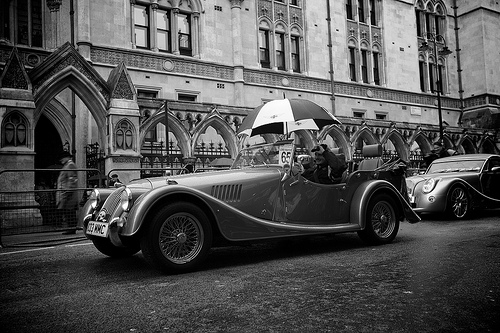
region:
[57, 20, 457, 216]
the photo is in black and white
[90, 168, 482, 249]
the car is antique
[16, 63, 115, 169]
the doorway is arched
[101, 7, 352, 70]
windows are on the building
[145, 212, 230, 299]
the wheels have chrome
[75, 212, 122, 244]
the license plate is on the front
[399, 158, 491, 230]
a car is behind the first car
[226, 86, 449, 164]
the man is holding an umbrella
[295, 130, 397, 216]
a man is saving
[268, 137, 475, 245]
the man is driving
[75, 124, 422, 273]
Man driving an old sports car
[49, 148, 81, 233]
A man is on the sidewalk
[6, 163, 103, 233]
A metal barricade on the sidewalk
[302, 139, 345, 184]
Driver waving to the crowd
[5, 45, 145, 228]
Archway on the sidewalk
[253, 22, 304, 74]
Windows on the building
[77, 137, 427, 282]
Car driving on the asphalt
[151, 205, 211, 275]
Car has metallic rims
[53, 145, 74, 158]
Man wearing a hat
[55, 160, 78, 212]
Man wearing a coat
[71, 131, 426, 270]
vintage car parked next to building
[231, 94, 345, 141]
black and white umbrella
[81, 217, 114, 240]
black and white license plate on front of car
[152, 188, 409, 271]
two wheels on side of vintage car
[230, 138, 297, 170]
windshield on vintage car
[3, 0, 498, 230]
stone building in front of sidewalk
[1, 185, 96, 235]
short metal fence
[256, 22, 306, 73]
three windows on front of building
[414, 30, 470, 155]
black street lamp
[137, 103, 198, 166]
arched design on stone wall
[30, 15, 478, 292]
black and white photograph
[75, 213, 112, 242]
license plate on front of car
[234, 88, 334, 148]
unbrella above people in car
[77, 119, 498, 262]
two old fashioned cars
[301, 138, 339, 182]
person driving the car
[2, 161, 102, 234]
metal gates along the side of the road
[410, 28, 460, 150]
old fashioned street light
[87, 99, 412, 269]
convertible car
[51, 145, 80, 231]
man standing on sidewalk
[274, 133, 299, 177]
the number 65 in the car window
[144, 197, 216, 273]
wheel of a car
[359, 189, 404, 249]
wheel of a car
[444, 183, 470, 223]
wheel of a car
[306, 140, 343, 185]
person in a car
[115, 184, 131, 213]
headlight on a car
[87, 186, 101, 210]
headlight on a car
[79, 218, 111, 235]
license plate on a car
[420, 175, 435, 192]
headlight on a car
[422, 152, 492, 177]
windshield on a car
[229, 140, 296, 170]
windshield on a car